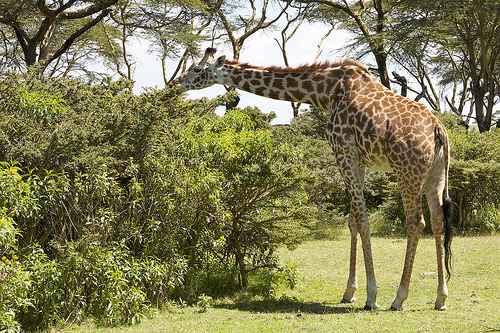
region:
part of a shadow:
[249, 302, 254, 323]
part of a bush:
[131, 196, 146, 219]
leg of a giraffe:
[367, 206, 384, 248]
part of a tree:
[166, 149, 201, 191]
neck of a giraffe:
[294, 83, 299, 89]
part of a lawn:
[312, 265, 327, 301]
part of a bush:
[108, 194, 126, 223]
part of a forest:
[127, 188, 154, 237]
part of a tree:
[430, 97, 442, 108]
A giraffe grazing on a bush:
[157, 38, 253, 108]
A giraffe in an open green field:
[165, 45, 491, 324]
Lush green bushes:
[33, 101, 213, 290]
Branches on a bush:
[217, 189, 264, 311]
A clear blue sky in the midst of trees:
[238, 6, 371, 59]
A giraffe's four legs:
[336, 213, 447, 319]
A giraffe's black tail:
[439, 133, 456, 283]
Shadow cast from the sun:
[209, 291, 363, 321]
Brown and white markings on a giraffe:
[274, 73, 349, 97]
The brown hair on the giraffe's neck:
[238, 60, 375, 73]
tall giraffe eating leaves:
[194, 42, 498, 275]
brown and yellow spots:
[374, 97, 421, 139]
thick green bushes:
[48, 84, 313, 328]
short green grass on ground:
[278, 233, 450, 331]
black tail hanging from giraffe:
[426, 133, 478, 265]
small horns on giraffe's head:
[193, 37, 218, 65]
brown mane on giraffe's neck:
[266, 47, 370, 74]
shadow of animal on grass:
[242, 289, 374, 327]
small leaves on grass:
[462, 282, 479, 303]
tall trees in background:
[308, 8, 493, 117]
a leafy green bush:
[0, 88, 230, 329]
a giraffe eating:
[168, 52, 453, 313]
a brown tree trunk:
[16, 0, 133, 88]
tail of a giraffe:
[436, 128, 459, 281]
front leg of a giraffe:
[343, 145, 380, 312]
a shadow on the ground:
[215, 293, 397, 321]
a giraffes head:
[157, 44, 227, 101]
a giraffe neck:
[233, 65, 320, 102]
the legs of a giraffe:
[336, 94, 461, 317]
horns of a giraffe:
[197, 46, 227, 67]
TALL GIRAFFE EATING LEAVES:
[194, 39, 461, 272]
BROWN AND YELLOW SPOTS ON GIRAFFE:
[346, 67, 428, 147]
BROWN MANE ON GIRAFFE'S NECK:
[244, 49, 369, 81]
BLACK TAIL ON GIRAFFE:
[427, 131, 459, 281]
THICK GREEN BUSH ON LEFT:
[16, 102, 310, 327]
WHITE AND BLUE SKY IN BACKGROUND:
[137, 30, 381, 103]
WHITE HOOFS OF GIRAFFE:
[329, 269, 498, 323]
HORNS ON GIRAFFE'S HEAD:
[189, 32, 239, 79]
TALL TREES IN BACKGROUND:
[332, 27, 499, 117]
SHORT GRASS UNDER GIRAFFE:
[278, 211, 492, 324]